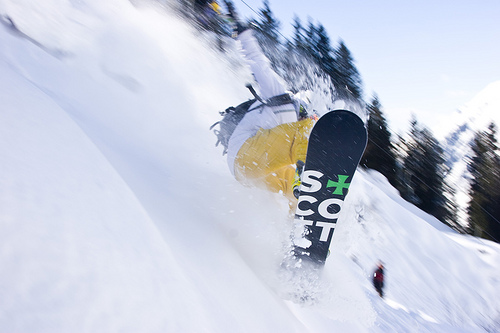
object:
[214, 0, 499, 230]
sky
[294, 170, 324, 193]
letters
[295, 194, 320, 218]
letters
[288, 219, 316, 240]
letters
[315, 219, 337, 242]
letters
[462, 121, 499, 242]
pine tree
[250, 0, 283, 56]
trees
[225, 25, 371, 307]
snowboarding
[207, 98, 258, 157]
back bag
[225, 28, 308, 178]
white jacket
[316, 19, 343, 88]
trees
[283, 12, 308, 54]
trees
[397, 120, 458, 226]
trees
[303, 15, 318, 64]
trees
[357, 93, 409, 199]
trees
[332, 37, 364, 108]
trees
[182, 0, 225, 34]
trees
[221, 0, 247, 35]
trees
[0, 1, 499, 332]
ground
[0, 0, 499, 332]
snow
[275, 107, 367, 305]
board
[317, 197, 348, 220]
lettering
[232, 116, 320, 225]
pants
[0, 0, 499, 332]
mountain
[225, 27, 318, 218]
snowsuit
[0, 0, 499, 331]
tracks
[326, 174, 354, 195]
cross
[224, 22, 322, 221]
he